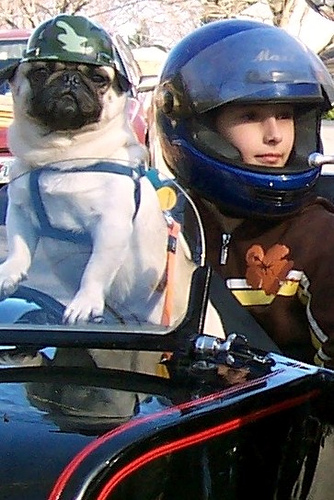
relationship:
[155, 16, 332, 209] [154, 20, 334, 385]
helmet on girl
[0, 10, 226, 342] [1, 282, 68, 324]
dog behind wheel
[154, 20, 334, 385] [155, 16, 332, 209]
girl with helmet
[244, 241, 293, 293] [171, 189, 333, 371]
flower on brown jacket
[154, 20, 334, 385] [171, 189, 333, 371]
girl with brown jacket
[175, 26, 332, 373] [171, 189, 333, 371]
girl wearing brown jacket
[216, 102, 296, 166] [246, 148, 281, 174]
face has mouth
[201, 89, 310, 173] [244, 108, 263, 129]
face has eye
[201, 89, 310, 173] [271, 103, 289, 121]
face has eye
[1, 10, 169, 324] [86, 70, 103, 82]
dog has eye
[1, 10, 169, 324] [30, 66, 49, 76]
dog has eye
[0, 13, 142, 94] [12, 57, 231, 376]
hat on dog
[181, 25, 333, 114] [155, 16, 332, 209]
shield on helmet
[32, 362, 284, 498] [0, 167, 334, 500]
stripe on car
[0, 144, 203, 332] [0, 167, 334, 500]
windshield on car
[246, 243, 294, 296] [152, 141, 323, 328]
flower on jacket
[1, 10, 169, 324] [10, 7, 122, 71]
dog wearing helmet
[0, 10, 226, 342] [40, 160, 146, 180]
dog wearing harness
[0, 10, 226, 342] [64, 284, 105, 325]
dog has paw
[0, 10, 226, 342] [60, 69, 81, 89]
dog has nose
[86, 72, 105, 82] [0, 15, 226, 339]
eye on dog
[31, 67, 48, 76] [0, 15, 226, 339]
eye on dog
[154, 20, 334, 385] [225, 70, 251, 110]
girl wearing helmet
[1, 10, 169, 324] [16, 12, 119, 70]
dog wearing helmet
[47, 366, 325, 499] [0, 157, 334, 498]
stripe on car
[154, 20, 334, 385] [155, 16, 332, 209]
girl wearing helmet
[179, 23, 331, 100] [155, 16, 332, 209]
face shield on helmet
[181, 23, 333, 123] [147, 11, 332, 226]
shield on helmet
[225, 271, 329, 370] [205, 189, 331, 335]
stripe on brown jacket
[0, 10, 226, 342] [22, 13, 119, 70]
dog wearing hat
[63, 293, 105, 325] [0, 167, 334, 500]
paw on car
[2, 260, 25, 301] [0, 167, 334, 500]
paws on car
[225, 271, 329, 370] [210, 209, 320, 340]
stripe on sweater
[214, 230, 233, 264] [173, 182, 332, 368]
zipper on sweater